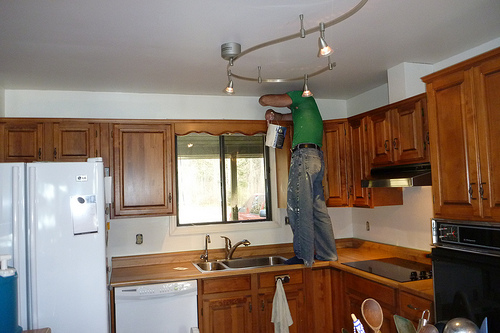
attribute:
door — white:
[114, 285, 200, 331]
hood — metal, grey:
[358, 160, 430, 189]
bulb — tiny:
[299, 90, 314, 98]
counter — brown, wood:
[122, 240, 199, 291]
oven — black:
[428, 215, 498, 328]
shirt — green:
[286, 88, 324, 147]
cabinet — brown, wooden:
[97, 117, 174, 222]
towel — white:
[268, 277, 290, 331]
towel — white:
[267, 276, 294, 331]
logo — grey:
[75, 173, 87, 180]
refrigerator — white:
[0, 157, 112, 332]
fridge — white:
[2, 138, 132, 331]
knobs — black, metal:
[466, 180, 486, 198]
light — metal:
[300, 81, 310, 97]